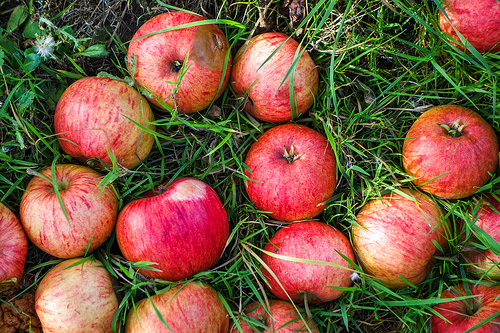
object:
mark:
[186, 24, 229, 73]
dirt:
[0, 273, 46, 333]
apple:
[113, 176, 231, 286]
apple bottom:
[44, 177, 69, 194]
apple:
[240, 121, 340, 223]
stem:
[23, 166, 63, 193]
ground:
[0, 0, 499, 333]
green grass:
[0, 0, 499, 333]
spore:
[29, 31, 57, 62]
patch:
[160, 178, 210, 203]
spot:
[210, 31, 226, 51]